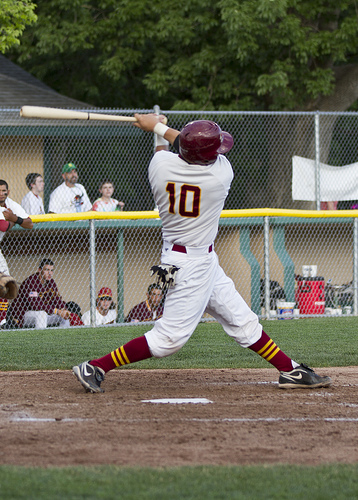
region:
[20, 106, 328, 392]
a baseball player swinging his bat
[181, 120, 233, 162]
man wearing a red hard hat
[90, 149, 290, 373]
man wearing a white, red and yellow uniform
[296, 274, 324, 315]
a red cooler with a black lid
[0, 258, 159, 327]
baseball player waiting in the dugout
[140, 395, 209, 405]
a white home plate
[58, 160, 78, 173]
man wearing a green cap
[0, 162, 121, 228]
spectators watching a baseball game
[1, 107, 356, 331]
a metal fence on a baseball field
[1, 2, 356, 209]
a big green lush tree on the other side of a fence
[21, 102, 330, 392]
a player holding a bat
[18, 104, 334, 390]
a player swinging a bat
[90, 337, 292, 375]
maroon socks with yellow stripes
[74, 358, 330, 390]
black and white baseball cleats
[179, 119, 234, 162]
a burgundy protective helmet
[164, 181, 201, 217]
a "10" written on back of jersey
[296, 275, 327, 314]
a red and black cooler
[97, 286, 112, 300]
a red player baseball cap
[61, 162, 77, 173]
a green ball cap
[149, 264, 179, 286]
pair of black and white gloves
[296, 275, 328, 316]
a red and black drink cooler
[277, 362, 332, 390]
a black and white baseball cleat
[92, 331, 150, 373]
a red sock with yellow stripes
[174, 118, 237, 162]
a maroon helmet on a batter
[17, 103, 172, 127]
a wooden bat in a man's hands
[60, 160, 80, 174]
a green cap on a man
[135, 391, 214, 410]
white home plate underneath a man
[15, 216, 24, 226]
a black wristband on a man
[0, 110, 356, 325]
a chain link fence at a baseball field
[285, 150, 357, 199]
a white banner on a fence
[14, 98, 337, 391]
Man swinging baseball bat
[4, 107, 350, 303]
silver chain link fence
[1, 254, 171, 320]
players sitting in dugout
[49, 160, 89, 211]
man with a green hat and white t-shirt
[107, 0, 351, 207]
large green tree with enormous trunk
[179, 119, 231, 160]
dark red batting helmet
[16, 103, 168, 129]
a light colored wooden bat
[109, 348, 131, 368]
yellow stripes on red stirrups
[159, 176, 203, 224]
number 10 on back of baseball jersey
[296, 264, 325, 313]
white cups on top of red and black water cooler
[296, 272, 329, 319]
a red water cooler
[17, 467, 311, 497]
grass on the baseball field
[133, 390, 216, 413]
a plate on the baseball field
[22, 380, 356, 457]
dirt on the baseball field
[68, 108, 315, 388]
a baseball player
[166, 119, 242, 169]
a man wearing a red helmet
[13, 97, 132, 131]
the bat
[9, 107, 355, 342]
a chain link fence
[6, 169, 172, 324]
people watching the baseball game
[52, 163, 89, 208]
a person in a green hat